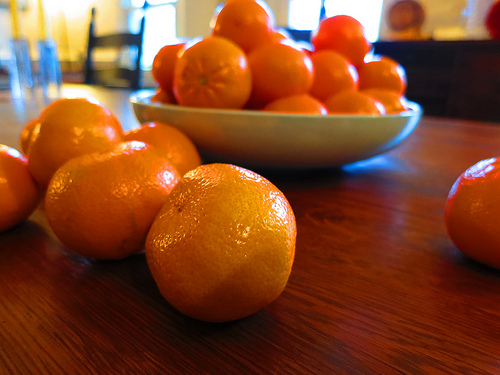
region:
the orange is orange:
[154, 164, 299, 316]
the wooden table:
[335, 294, 428, 359]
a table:
[326, 271, 399, 350]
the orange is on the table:
[164, 192, 296, 310]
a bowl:
[256, 113, 299, 158]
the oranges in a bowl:
[178, 23, 368, 108]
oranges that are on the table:
[46, 122, 298, 312]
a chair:
[78, 33, 150, 87]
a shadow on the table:
[461, 157, 491, 182]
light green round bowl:
[131, 95, 423, 172]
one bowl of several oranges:
[127, 4, 422, 172]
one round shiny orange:
[148, 162, 296, 325]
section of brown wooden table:
[310, 179, 434, 352]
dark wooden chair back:
[73, 1, 149, 89]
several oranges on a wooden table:
[2, 103, 292, 374]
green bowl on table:
[126, 89, 426, 214]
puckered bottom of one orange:
[183, 57, 233, 100]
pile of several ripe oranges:
[163, 3, 409, 113]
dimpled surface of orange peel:
[198, 177, 260, 242]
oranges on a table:
[22, 76, 304, 370]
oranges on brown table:
[36, 69, 246, 364]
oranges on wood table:
[46, 66, 261, 366]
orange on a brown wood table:
[82, 93, 411, 365]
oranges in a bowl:
[157, 8, 497, 176]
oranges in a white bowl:
[154, 11, 487, 215]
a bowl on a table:
[151, 25, 399, 170]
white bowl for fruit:
[131, 88, 427, 168]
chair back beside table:
[85, 0, 150, 95]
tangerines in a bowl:
[146, 0, 411, 171]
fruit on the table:
[40, 140, 290, 310]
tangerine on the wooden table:
[140, 155, 295, 325]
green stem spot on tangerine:
[191, 69, 211, 89]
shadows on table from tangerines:
[3, 217, 54, 284]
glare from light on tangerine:
[121, 135, 191, 199]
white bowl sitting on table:
[126, 77, 423, 182]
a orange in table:
[161, 175, 310, 330]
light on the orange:
[251, 201, 284, 244]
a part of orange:
[160, 179, 204, 231]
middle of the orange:
[149, 182, 209, 238]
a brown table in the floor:
[303, 223, 427, 350]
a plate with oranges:
[124, 15, 458, 151]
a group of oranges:
[157, 20, 466, 139]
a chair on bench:
[54, 19, 149, 84]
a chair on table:
[53, 29, 185, 91]